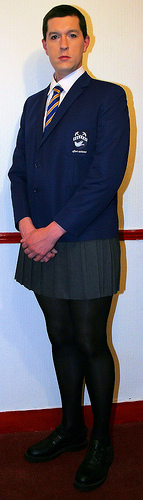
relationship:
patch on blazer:
[71, 129, 88, 153] [14, 68, 142, 204]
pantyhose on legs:
[40, 292, 122, 414] [23, 274, 125, 441]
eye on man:
[68, 33, 76, 38] [10, 4, 123, 490]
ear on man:
[83, 36, 88, 51] [24, 12, 132, 159]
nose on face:
[59, 36, 69, 54] [42, 8, 87, 69]